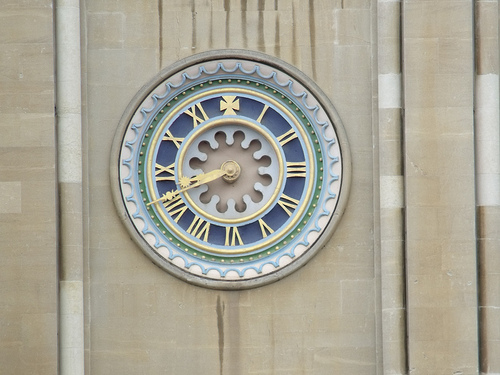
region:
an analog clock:
[86, 33, 381, 304]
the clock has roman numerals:
[79, 28, 362, 322]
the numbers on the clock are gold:
[106, 58, 368, 315]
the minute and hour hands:
[117, 158, 278, 215]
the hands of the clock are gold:
[116, 27, 348, 296]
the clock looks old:
[94, 12, 384, 344]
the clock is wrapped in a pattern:
[96, 12, 378, 334]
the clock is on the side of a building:
[104, 10, 370, 327]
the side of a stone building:
[1, 3, 497, 373]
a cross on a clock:
[212, 88, 247, 125]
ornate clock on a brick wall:
[107, 49, 351, 290]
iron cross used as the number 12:
[218, 94, 240, 114]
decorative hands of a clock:
[147, 160, 240, 207]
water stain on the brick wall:
[215, 295, 230, 374]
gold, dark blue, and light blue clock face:
[145, 85, 317, 255]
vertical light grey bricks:
[53, 0, 83, 373]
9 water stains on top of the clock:
[151, 0, 321, 82]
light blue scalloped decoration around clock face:
[120, 60, 339, 277]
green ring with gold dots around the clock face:
[138, 78, 323, 265]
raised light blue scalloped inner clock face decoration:
[181, 123, 280, 218]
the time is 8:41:
[107, 43, 348, 290]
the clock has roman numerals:
[105, 45, 356, 290]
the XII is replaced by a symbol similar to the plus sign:
[215, 87, 241, 122]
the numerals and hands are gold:
[133, 82, 318, 257]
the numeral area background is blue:
[142, 82, 315, 263]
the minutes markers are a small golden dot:
[127, 75, 328, 267]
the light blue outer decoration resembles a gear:
[117, 60, 342, 283]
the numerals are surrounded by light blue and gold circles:
[140, 78, 317, 256]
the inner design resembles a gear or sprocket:
[185, 125, 280, 215]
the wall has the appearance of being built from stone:
[1, 1, 496, 373]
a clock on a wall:
[107, 54, 370, 310]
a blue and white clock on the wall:
[120, 61, 335, 277]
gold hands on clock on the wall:
[143, 158, 240, 219]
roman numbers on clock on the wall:
[215, 201, 320, 251]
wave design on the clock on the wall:
[180, 126, 287, 212]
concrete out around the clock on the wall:
[75, 55, 391, 331]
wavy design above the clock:
[145, 0, 337, 75]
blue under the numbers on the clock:
[146, 90, 311, 246]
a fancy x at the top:
[220, 90, 251, 118]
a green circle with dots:
[134, 75, 320, 260]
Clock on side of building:
[72, 25, 383, 307]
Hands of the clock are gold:
[152, 120, 246, 233]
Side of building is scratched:
[334, 261, 430, 372]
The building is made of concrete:
[13, 102, 110, 347]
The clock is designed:
[137, 68, 354, 296]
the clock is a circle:
[84, 27, 366, 307]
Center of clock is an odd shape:
[168, 143, 278, 200]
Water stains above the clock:
[133, 10, 365, 70]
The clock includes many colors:
[74, 21, 379, 331]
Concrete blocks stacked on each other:
[30, 28, 113, 372]